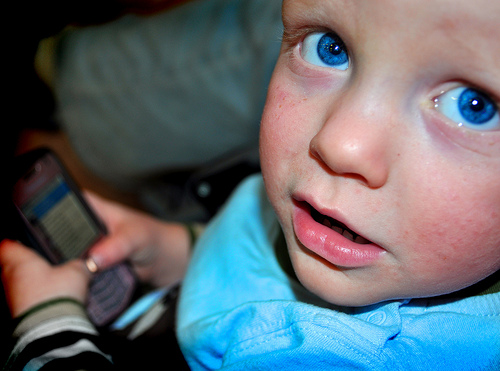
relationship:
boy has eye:
[2, 0, 499, 370] [429, 83, 499, 133]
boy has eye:
[2, 0, 499, 370] [297, 29, 352, 71]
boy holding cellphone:
[2, 0, 499, 366] [3, 143, 138, 331]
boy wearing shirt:
[2, 0, 499, 366] [180, 170, 499, 368]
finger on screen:
[89, 226, 138, 262] [20, 161, 136, 325]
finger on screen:
[62, 258, 95, 281] [20, 161, 136, 325]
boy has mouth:
[2, 0, 499, 370] [286, 188, 387, 269]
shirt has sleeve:
[0, 166, 196, 371] [180, 218, 209, 260]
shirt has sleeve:
[0, 166, 196, 371] [6, 291, 121, 370]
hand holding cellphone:
[81, 188, 181, 288] [3, 143, 138, 331]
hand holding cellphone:
[0, 238, 89, 317] [3, 143, 138, 331]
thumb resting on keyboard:
[86, 224, 137, 266] [85, 263, 129, 319]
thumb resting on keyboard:
[58, 254, 93, 280] [85, 263, 129, 319]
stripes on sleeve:
[14, 298, 111, 368] [0, 291, 121, 371]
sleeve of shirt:
[0, 291, 121, 371] [6, 166, 498, 364]